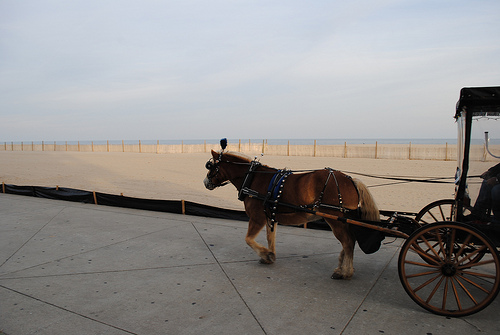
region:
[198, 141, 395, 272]
brown horse pulling wagon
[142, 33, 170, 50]
white clouds in blue sky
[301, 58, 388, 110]
white clouds in blue sky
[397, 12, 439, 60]
white clouds in blue sky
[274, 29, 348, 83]
white clouds in blue sky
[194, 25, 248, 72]
white clouds in blue sky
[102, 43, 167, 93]
white clouds in blue sky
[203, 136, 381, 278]
A brown colored horse.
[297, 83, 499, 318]
A horse drawn cart.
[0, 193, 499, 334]
A gray cement sidewalk.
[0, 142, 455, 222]
A long sandy beach.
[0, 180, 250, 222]
A black plastic barrier.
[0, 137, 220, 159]
Wood and wire fencing.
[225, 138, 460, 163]
Fencing on a beach.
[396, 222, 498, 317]
Brown and black wheel.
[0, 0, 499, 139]
A background of sky.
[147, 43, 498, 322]
this is a horse drawn carriage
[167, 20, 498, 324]
a horse drawn buggy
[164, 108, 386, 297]
this is a miniature horse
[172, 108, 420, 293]
the horse is harnessed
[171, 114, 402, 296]
the horse has a brown hide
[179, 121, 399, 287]
the horse is brown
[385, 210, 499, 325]
a large wooden wheel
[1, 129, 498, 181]
this is a long fence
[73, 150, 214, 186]
this is sand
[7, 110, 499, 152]
this is the ocean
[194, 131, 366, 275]
brown horse pulling wagon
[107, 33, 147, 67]
white clouds in blue sky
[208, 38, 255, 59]
white clouds in blue sky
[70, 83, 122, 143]
white clouds in blue sky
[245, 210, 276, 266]
the leg of a horse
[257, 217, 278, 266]
the leg of a horse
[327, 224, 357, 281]
the legs of a horse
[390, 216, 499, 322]
the wheel of a carriage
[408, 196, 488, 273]
the wheel of a carriage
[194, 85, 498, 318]
a horse pulling a carriage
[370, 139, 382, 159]
a wooden post on a fence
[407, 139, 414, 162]
a wooden post on a fence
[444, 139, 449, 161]
a wooden post on a fence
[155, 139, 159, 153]
a wooden post on a fence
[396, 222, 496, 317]
large round wheel on buggy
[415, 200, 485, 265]
large round wheel on buggy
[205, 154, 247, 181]
black harness on horse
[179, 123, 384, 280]
brown horse pulling cart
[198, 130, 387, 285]
brown horse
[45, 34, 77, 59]
white clouds in blue sky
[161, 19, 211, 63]
white clouds in blue sky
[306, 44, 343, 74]
white clouds in blue sky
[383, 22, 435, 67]
white clouds in blue sky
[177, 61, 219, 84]
white clouds in blue sky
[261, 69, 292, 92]
white clouds in blue sky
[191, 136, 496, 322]
a horse pulling a buggy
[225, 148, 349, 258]
a horse wearing a harness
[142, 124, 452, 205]
a fence on the beach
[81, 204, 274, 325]
a cement sidewalk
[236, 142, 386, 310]
a brown horse on the sidewalk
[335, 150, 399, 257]
a tail on the horse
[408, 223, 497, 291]
a wheel ont he carraige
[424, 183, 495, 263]
a wheel on the carriage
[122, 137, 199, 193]
an area of the sand